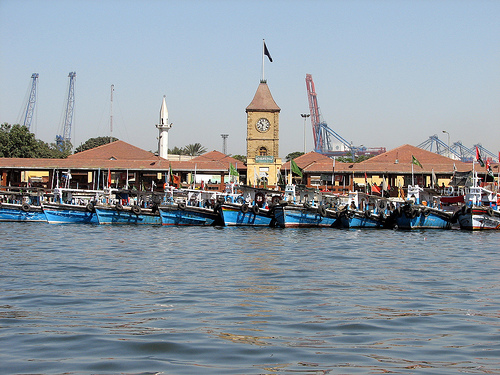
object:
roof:
[280, 144, 500, 174]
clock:
[255, 117, 271, 133]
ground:
[408, 68, 474, 152]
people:
[276, 180, 445, 193]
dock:
[0, 165, 499, 223]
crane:
[302, 73, 386, 163]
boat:
[0, 194, 47, 223]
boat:
[39, 189, 99, 223]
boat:
[94, 192, 162, 224]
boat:
[157, 190, 220, 226]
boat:
[217, 194, 273, 226]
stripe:
[0, 209, 42, 215]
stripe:
[47, 211, 91, 219]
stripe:
[98, 212, 143, 222]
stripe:
[162, 214, 206, 223]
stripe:
[286, 212, 322, 222]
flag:
[261, 38, 273, 81]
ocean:
[1, 222, 498, 375]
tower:
[154, 95, 173, 160]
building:
[0, 139, 246, 195]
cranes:
[56, 70, 77, 158]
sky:
[0, 0, 500, 153]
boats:
[0, 185, 500, 231]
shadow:
[235, 211, 278, 231]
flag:
[349, 171, 387, 194]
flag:
[411, 155, 423, 187]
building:
[245, 79, 281, 191]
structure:
[0, 140, 500, 232]